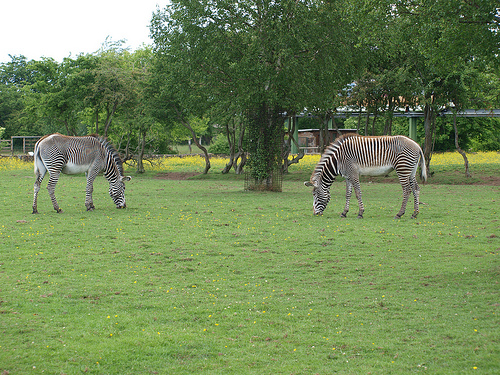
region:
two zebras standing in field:
[20, 119, 432, 236]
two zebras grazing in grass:
[11, 125, 433, 224]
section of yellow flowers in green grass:
[9, 226, 67, 278]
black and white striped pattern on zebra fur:
[355, 142, 397, 160]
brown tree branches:
[182, 133, 244, 178]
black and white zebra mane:
[95, 131, 125, 177]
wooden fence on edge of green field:
[4, 129, 62, 164]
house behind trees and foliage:
[285, 66, 434, 164]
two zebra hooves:
[339, 203, 369, 220]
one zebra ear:
[122, 170, 136, 186]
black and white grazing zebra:
[303, 131, 426, 218]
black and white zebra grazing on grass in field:
[30, 132, 127, 212]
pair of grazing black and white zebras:
[33, 131, 428, 221]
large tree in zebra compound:
[157, 0, 395, 193]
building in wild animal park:
[297, 128, 358, 155]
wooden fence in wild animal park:
[2, 135, 39, 155]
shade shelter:
[273, 105, 498, 117]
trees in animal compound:
[0, 0, 498, 193]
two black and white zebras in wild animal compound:
[0, 0, 499, 374]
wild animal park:
[0, 0, 496, 372]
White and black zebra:
[25, 117, 145, 228]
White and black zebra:
[298, 99, 440, 233]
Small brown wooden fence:
[4, 125, 55, 172]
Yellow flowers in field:
[98, 309, 134, 343]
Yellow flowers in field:
[150, 322, 167, 354]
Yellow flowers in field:
[193, 306, 234, 343]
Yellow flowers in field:
[233, 276, 290, 313]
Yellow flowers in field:
[453, 349, 476, 374]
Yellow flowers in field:
[448, 306, 487, 342]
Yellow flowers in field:
[182, 238, 223, 295]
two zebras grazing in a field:
[27, 130, 427, 222]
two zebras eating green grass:
[30, 132, 430, 236]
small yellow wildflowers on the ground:
[162, 271, 370, 356]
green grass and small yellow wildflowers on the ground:
[11, 228, 487, 367]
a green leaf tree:
[140, 1, 378, 190]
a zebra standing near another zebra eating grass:
[303, 130, 428, 220]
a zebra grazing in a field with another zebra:
[28, 133, 134, 217]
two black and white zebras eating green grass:
[29, 130, 429, 230]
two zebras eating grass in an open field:
[30, 130, 427, 290]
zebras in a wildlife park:
[1, 2, 496, 371]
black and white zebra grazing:
[301, 128, 438, 227]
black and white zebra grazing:
[27, 122, 138, 218]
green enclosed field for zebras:
[5, 160, 495, 360]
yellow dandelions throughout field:
[18, 137, 499, 173]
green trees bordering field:
[19, 0, 497, 180]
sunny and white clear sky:
[7, 0, 499, 68]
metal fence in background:
[246, 92, 498, 168]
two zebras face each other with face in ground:
[19, 104, 447, 230]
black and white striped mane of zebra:
[308, 124, 373, 175]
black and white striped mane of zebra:
[74, 126, 133, 176]